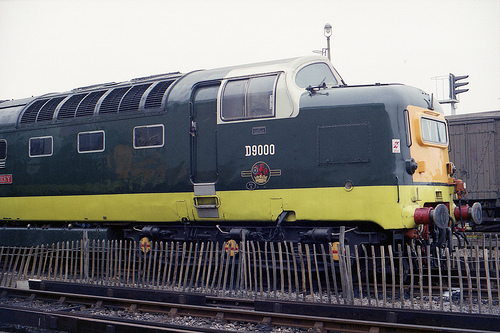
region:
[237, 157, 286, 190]
red and gold logo on train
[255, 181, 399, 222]
yellow stripe on green train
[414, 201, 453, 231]
black and red bumper on train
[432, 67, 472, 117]
steel cage above green train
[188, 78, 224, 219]
grey step under green door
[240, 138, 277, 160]
letter and number in white on train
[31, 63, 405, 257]
a black and yellow train car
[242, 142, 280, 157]
white numbers painted on a train car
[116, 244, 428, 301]
a fence with wood post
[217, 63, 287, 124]
a window in a train car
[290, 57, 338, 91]
windshield on a train car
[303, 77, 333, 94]
a windshield wiper on a train car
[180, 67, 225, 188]
a door way on a train car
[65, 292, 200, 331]
gravel next to a train track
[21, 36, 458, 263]
a train car stopped on a track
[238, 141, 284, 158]
numbers and letters on the train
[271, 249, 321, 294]
a fence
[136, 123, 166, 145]
a window on the train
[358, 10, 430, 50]
the sky is cloudy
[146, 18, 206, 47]
the cloudy sky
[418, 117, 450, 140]
a windshield on the train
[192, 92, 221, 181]
door on the train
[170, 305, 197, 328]
the train tracks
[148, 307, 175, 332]
small rocks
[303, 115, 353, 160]
the train is blue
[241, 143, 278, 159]
number on the side of a train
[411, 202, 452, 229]
right bumper on a train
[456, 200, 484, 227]
left bumper on a train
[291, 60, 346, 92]
windshield on a train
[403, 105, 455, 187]
yellow front of a train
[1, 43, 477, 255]
yellow and black train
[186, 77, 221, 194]
door on the side of the train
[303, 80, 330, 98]
windshield wiper on a train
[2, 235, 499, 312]
old broken fence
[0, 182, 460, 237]
yellow stripe on a train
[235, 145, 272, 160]
the numbers are white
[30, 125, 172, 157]
windows on the train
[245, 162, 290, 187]
logo on the train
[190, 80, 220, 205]
the door is green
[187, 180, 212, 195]
the step is silver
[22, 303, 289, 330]
the gravel is under tracks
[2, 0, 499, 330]
an image during the day time